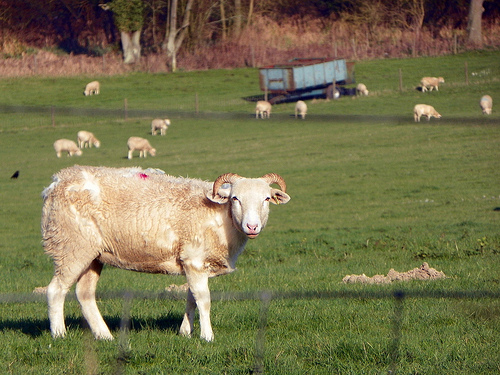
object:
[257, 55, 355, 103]
trailer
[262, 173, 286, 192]
horn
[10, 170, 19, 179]
bird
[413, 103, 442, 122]
sheep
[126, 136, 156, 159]
sheep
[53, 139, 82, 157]
sheep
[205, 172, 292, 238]
head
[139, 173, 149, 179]
marking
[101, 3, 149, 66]
tree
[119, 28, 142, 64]
trunk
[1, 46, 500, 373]
grass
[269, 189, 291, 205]
ear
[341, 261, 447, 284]
matter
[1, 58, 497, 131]
fence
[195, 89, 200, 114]
pole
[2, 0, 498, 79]
foilage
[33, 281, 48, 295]
dirt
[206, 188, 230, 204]
ear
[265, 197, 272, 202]
eye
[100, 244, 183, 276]
stomach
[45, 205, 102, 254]
hind thigh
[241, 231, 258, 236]
mouth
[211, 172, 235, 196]
horn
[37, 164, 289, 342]
goat